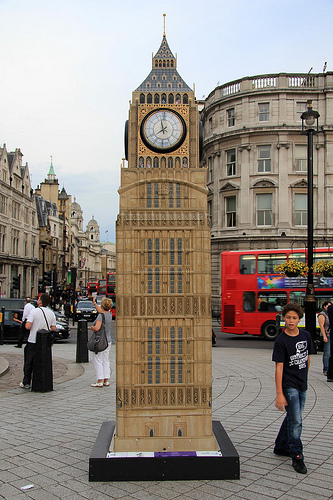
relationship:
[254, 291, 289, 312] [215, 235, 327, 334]
window on bus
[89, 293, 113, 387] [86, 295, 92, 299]
woman taking a picture with smartphone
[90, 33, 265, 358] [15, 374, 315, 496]
statue set in middle of pavement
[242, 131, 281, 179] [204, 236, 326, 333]
window on bus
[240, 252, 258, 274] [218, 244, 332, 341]
window on bus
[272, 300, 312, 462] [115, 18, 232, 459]
boy standing tower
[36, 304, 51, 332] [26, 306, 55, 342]
strap across shirt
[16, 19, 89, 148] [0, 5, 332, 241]
light in sky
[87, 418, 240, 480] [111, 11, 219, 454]
base of clock tower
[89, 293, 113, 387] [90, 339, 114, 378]
woman wearing white pants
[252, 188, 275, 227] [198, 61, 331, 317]
window on curved building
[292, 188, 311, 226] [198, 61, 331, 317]
window on curved building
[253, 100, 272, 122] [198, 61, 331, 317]
window on curved building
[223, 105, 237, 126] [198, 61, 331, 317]
window on curved building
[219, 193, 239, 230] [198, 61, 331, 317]
window on curved building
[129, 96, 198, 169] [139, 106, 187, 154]
clock with face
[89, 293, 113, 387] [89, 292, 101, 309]
woman with hand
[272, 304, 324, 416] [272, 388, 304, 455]
boy in jeans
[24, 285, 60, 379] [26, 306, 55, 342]
man in shirt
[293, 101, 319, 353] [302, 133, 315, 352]
light on post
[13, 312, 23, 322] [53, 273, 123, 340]
person sitting in car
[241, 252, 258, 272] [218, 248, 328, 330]
window of bus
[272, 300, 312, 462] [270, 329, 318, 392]
boy in shirt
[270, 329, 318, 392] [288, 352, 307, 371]
shirt with writing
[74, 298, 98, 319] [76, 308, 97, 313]
car with headlights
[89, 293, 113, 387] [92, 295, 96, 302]
woman raising hand